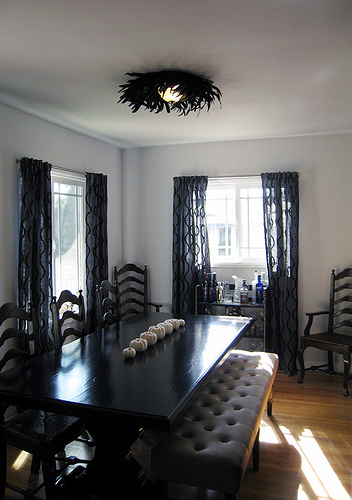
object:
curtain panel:
[259, 170, 298, 378]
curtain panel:
[172, 174, 210, 316]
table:
[0, 309, 253, 497]